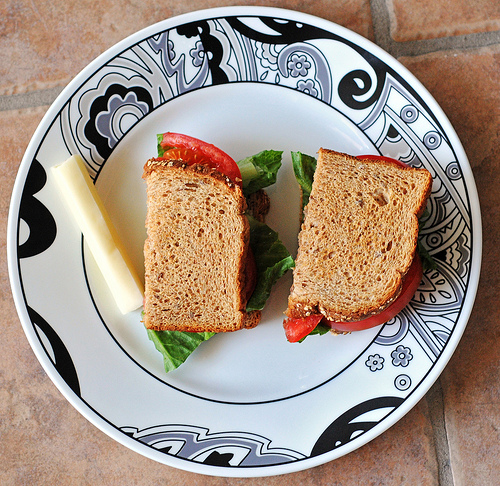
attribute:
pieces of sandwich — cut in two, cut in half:
[145, 135, 433, 374]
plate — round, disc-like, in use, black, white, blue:
[8, 7, 487, 476]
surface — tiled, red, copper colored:
[2, 0, 499, 485]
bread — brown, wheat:
[144, 160, 246, 334]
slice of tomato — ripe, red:
[162, 133, 239, 187]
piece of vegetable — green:
[291, 151, 318, 198]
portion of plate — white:
[84, 82, 389, 403]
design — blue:
[92, 16, 419, 87]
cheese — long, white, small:
[50, 157, 146, 318]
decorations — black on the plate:
[18, 156, 82, 398]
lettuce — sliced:
[243, 147, 318, 304]